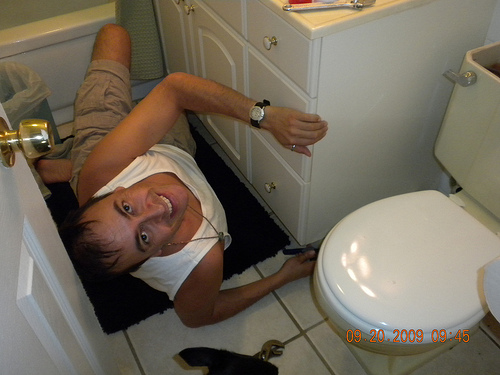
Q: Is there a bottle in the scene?
A: No, there are no bottles.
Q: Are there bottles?
A: No, there are no bottles.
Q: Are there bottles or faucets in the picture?
A: No, there are no bottles or faucets.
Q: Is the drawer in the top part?
A: Yes, the drawer is in the top of the image.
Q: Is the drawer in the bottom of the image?
A: No, the drawer is in the top of the image.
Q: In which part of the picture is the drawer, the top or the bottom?
A: The drawer is in the top of the image.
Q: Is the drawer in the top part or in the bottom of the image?
A: The drawer is in the top of the image.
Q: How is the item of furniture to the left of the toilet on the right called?
A: The piece of furniture is a drawer.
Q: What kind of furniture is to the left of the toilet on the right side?
A: The piece of furniture is a drawer.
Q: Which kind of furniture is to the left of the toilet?
A: The piece of furniture is a drawer.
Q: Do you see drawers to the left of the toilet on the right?
A: Yes, there is a drawer to the left of the toilet.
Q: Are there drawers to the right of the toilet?
A: No, the drawer is to the left of the toilet.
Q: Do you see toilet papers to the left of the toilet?
A: No, there is a drawer to the left of the toilet.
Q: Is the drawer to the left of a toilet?
A: Yes, the drawer is to the left of a toilet.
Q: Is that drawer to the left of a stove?
A: No, the drawer is to the left of a toilet.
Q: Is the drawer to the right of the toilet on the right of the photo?
A: No, the drawer is to the left of the toilet.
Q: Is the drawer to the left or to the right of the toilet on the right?
A: The drawer is to the left of the toilet.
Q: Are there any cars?
A: No, there are no cars.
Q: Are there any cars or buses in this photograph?
A: No, there are no cars or buses.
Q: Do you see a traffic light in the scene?
A: No, there are no traffic lights.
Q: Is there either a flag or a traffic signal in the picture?
A: No, there are no traffic lights or flags.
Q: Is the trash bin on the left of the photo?
A: Yes, the trash bin is on the left of the image.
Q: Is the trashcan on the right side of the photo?
A: No, the trashcan is on the left of the image.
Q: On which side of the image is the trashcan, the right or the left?
A: The trashcan is on the left of the image.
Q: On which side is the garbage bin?
A: The garbage bin is on the left of the image.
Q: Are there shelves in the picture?
A: No, there are no shelves.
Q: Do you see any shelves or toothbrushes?
A: No, there are no shelves or toothbrushes.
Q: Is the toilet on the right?
A: Yes, the toilet is on the right of the image.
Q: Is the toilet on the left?
A: No, the toilet is on the right of the image.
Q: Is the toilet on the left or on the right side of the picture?
A: The toilet is on the right of the image.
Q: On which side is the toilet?
A: The toilet is on the right of the image.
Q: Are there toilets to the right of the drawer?
A: Yes, there is a toilet to the right of the drawer.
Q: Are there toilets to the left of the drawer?
A: No, the toilet is to the right of the drawer.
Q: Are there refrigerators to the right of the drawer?
A: No, there is a toilet to the right of the drawer.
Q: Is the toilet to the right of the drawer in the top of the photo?
A: Yes, the toilet is to the right of the drawer.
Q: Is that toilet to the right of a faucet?
A: No, the toilet is to the right of the drawer.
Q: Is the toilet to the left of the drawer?
A: No, the toilet is to the right of the drawer.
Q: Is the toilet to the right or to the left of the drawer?
A: The toilet is to the right of the drawer.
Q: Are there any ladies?
A: No, there are no ladies.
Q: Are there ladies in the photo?
A: No, there are no ladies.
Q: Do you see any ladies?
A: No, there are no ladies.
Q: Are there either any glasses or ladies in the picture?
A: No, there are no ladies or glasses.